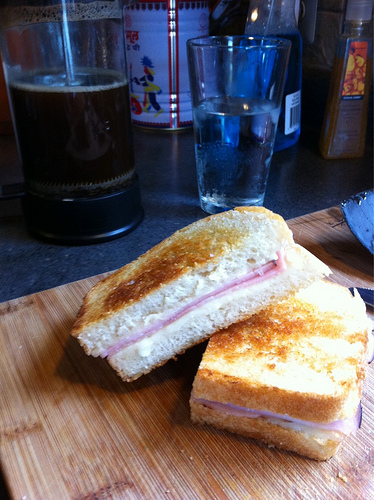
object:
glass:
[186, 37, 291, 215]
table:
[2, 123, 371, 303]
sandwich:
[69, 206, 312, 384]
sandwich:
[189, 280, 372, 461]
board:
[0, 202, 374, 499]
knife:
[345, 286, 373, 309]